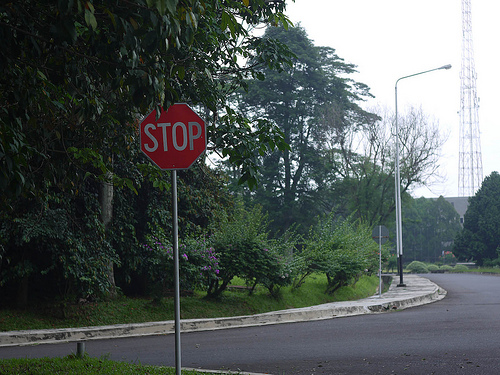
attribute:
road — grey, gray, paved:
[273, 343, 310, 353]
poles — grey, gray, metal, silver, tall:
[380, 204, 414, 220]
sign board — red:
[144, 105, 198, 169]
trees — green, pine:
[0, 46, 109, 153]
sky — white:
[320, 7, 360, 28]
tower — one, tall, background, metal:
[452, 165, 485, 200]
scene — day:
[323, 129, 347, 159]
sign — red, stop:
[156, 109, 187, 166]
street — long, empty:
[289, 320, 366, 347]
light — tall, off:
[389, 221, 404, 276]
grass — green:
[98, 305, 142, 324]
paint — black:
[395, 261, 401, 276]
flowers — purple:
[182, 248, 218, 270]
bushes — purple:
[211, 240, 311, 294]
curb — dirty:
[222, 321, 251, 336]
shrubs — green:
[117, 273, 169, 295]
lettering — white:
[147, 122, 193, 146]